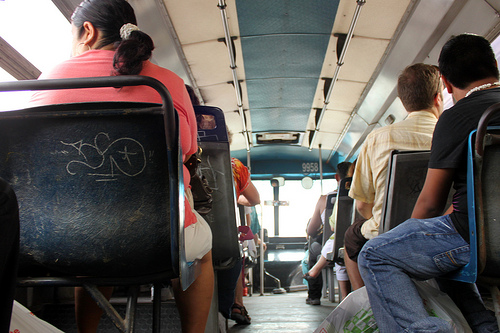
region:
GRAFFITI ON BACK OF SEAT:
[60, 135, 157, 183]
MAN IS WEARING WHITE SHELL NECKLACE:
[464, 81, 499, 98]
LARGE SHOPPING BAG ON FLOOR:
[309, 273, 475, 331]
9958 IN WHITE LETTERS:
[300, 160, 322, 173]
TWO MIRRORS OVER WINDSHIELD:
[269, 176, 314, 188]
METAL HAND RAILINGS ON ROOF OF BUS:
[207, 1, 369, 150]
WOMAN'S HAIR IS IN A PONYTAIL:
[71, 0, 155, 85]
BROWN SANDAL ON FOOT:
[229, 300, 253, 325]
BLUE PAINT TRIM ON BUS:
[254, 149, 292, 171]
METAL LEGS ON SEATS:
[82, 281, 160, 331]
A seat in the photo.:
[2, 74, 179, 286]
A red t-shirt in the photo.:
[30, 42, 201, 223]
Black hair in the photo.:
[65, 0, 158, 70]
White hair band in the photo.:
[119, 24, 144, 45]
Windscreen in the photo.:
[256, 182, 311, 237]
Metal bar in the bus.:
[212, 5, 247, 86]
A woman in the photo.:
[27, 0, 217, 272]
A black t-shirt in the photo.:
[427, 86, 497, 226]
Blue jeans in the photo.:
[356, 215, 471, 329]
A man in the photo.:
[354, 32, 495, 331]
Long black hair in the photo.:
[67, 0, 152, 69]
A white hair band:
[115, 22, 142, 42]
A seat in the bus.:
[0, 78, 172, 277]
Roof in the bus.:
[253, 3, 323, 133]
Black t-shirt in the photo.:
[430, 100, 485, 219]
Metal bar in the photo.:
[225, 39, 255, 115]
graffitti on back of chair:
[57, 128, 152, 180]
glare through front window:
[247, 179, 334, 236]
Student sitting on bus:
[38, 1, 210, 329]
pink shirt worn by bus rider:
[21, 51, 198, 226]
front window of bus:
[237, 176, 340, 235]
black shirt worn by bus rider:
[416, 88, 496, 218]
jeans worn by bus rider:
[350, 214, 470, 324]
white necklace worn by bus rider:
[463, 81, 498, 96]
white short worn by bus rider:
[178, 189, 213, 271]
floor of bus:
[240, 291, 332, 332]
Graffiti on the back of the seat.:
[56, 129, 148, 186]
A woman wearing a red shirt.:
[27, 0, 214, 332]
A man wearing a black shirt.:
[412, 33, 499, 331]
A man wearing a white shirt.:
[348, 63, 443, 238]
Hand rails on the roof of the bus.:
[306, 0, 367, 152]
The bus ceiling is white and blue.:
[166, 0, 418, 150]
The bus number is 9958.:
[300, 161, 319, 174]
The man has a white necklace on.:
[437, 32, 499, 99]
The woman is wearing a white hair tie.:
[65, 1, 155, 78]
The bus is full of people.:
[1, 0, 498, 330]